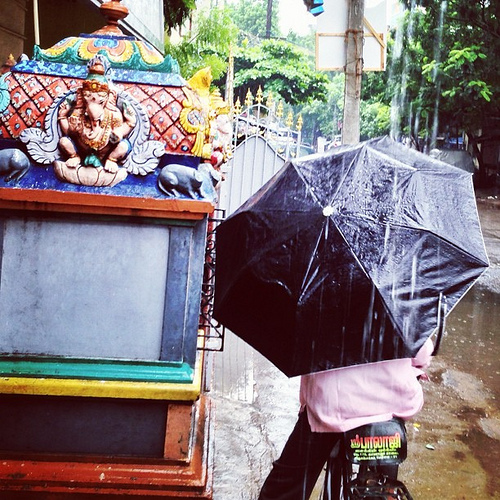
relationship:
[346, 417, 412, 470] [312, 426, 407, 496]
back of bicycle